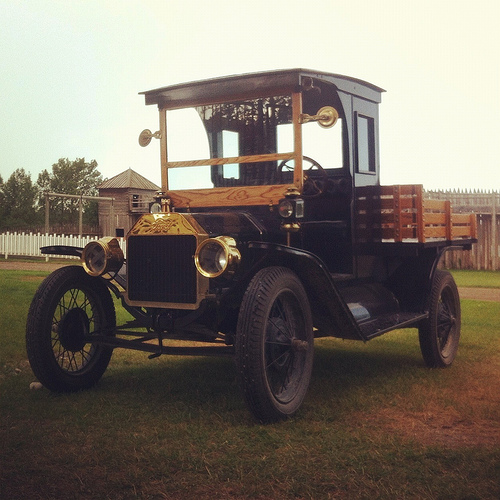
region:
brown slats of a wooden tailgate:
[380, 184, 475, 239]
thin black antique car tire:
[235, 264, 314, 416]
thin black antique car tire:
[418, 271, 460, 366]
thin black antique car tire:
[25, 265, 117, 390]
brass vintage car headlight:
[80, 235, 124, 277]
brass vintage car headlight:
[192, 236, 239, 277]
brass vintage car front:
[123, 212, 208, 308]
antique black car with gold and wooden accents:
[26, 68, 478, 422]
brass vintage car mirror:
[139, 128, 161, 145]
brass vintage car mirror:
[301, 105, 338, 126]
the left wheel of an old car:
[227, 280, 339, 445]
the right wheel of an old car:
[30, 267, 112, 399]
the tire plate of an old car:
[59, 310, 94, 347]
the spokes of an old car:
[67, 284, 91, 309]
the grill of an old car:
[126, 234, 195, 304]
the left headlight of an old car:
[196, 235, 248, 279]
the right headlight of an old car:
[63, 237, 120, 276]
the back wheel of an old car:
[402, 278, 456, 362]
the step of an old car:
[345, 302, 415, 352]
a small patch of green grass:
[83, 417, 177, 477]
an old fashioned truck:
[25, 64, 478, 419]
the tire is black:
[237, 265, 313, 417]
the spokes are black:
[265, 290, 302, 404]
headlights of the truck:
[82, 238, 239, 278]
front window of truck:
[162, 95, 294, 187]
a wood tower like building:
[98, 170, 158, 235]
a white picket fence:
[1, 230, 125, 261]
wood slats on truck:
[380, 185, 475, 240]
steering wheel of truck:
[276, 154, 324, 198]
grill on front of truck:
[126, 238, 196, 303]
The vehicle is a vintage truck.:
[22, 68, 477, 418]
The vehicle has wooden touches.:
[178, 185, 285, 205]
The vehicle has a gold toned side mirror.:
[298, 105, 338, 128]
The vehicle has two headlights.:
[81, 238, 230, 278]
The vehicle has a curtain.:
[239, 100, 272, 155]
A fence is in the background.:
[482, 190, 497, 270]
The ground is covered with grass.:
[38, 402, 209, 499]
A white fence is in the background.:
[1, 232, 38, 259]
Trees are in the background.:
[0, 158, 100, 188]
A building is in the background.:
[100, 168, 135, 219]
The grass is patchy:
[143, 417, 216, 497]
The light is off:
[158, 219, 290, 318]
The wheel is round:
[175, 216, 346, 418]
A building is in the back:
[86, 157, 173, 275]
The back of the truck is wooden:
[361, 160, 487, 275]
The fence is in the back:
[421, 168, 498, 278]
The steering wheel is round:
[273, 147, 331, 238]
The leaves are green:
[12, 162, 78, 217]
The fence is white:
[7, 227, 135, 293]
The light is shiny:
[74, 233, 131, 285]